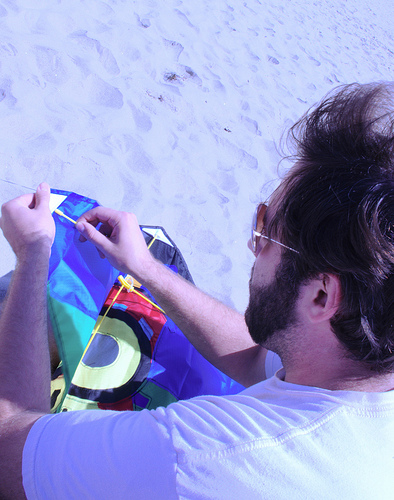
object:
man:
[0, 77, 394, 498]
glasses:
[244, 194, 353, 285]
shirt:
[18, 371, 393, 500]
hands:
[0, 183, 55, 249]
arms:
[0, 261, 166, 499]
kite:
[17, 182, 245, 427]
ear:
[305, 267, 342, 326]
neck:
[267, 334, 394, 393]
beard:
[242, 258, 305, 347]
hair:
[276, 77, 393, 361]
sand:
[0, 1, 393, 323]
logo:
[66, 304, 154, 404]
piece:
[52, 201, 76, 233]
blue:
[154, 312, 246, 401]